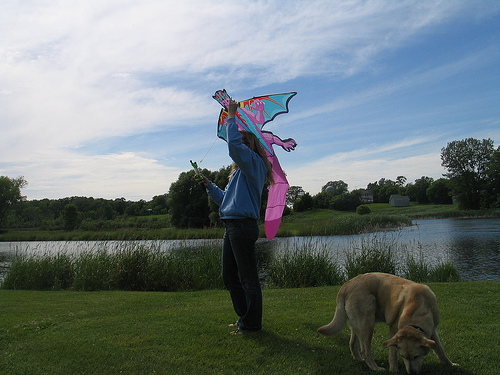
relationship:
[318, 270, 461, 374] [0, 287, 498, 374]
dog sniffing grass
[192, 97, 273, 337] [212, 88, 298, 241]
girl holding kite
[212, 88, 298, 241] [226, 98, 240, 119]
kite in hand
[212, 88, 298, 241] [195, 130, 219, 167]
kite has string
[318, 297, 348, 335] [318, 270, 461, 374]
tail of dog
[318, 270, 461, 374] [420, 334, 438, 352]
dog has ear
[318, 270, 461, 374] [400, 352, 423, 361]
dog has eyes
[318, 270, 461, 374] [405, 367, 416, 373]
dog has nose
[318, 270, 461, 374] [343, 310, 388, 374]
dog has legs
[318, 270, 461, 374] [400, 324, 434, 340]
dog has collar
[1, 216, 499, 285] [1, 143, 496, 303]
water in background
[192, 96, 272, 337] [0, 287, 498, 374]
girl in grass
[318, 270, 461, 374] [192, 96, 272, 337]
dog beside girl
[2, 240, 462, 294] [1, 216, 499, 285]
reeds beside water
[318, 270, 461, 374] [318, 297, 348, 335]
dog has tail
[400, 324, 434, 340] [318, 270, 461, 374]
collar on dog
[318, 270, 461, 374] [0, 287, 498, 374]
dog in grass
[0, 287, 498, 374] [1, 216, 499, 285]
grass near water